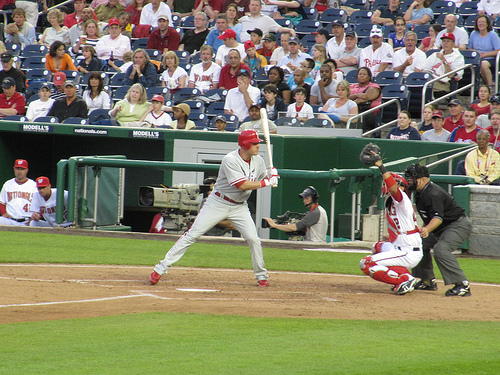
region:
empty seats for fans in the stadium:
[285, 5, 375, 42]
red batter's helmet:
[233, 129, 263, 149]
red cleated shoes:
[148, 263, 270, 290]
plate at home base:
[173, 281, 220, 297]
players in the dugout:
[1, 114, 132, 225]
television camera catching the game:
[138, 182, 215, 210]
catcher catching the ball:
[359, 129, 428, 304]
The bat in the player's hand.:
[259, 107, 278, 178]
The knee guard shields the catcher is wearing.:
[358, 256, 413, 289]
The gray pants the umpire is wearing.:
[424, 220, 471, 286]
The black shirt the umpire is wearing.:
[417, 179, 460, 227]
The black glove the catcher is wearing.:
[361, 145, 380, 165]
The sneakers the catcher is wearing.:
[391, 274, 417, 293]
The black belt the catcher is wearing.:
[394, 243, 421, 252]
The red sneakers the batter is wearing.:
[149, 269, 269, 289]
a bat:
[261, 109, 283, 181]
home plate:
[174, 267, 229, 297]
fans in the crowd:
[256, 38, 350, 98]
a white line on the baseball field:
[93, 290, 133, 302]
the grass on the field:
[190, 318, 250, 372]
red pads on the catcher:
[373, 267, 390, 284]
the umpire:
[414, 165, 472, 227]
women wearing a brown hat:
[170, 100, 197, 123]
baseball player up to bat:
[156, 100, 303, 309]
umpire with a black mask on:
[401, 163, 476, 300]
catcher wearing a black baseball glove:
[346, 133, 425, 298]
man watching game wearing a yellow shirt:
[454, 125, 499, 182]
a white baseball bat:
[254, 100, 284, 182]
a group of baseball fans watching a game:
[6, 5, 498, 133]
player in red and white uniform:
[180, 126, 312, 294]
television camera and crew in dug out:
[144, 175, 331, 240]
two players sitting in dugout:
[2, 148, 62, 232]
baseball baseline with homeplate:
[31, 250, 496, 332]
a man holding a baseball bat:
[254, 106, 279, 191]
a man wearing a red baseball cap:
[10, 157, 30, 174]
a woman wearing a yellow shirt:
[469, 133, 496, 176]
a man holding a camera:
[263, 187, 321, 234]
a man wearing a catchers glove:
[357, 142, 385, 172]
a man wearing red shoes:
[145, 266, 167, 287]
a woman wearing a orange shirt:
[45, 38, 70, 73]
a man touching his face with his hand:
[317, 59, 334, 91]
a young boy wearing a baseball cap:
[206, 112, 230, 136]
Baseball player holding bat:
[148, 109, 280, 287]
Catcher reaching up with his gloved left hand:
[355, 141, 425, 296]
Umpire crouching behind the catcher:
[403, 162, 473, 297]